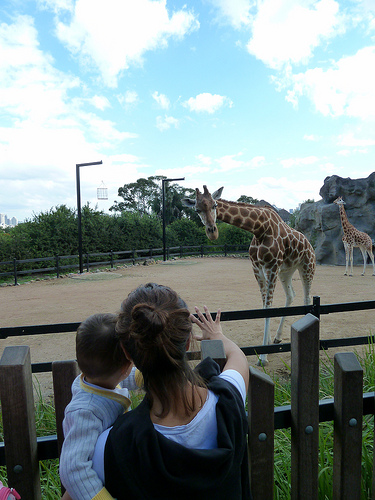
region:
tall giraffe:
[189, 191, 324, 291]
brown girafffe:
[321, 195, 367, 267]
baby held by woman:
[38, 310, 138, 476]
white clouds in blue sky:
[15, 13, 81, 86]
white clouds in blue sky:
[11, 70, 65, 134]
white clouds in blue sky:
[13, 132, 56, 185]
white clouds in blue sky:
[95, 32, 168, 139]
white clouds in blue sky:
[189, 105, 223, 141]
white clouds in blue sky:
[243, 42, 281, 91]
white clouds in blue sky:
[197, 95, 275, 152]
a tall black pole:
[73, 157, 112, 268]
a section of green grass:
[2, 355, 373, 498]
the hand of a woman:
[190, 306, 229, 341]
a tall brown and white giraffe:
[191, 181, 320, 369]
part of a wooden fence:
[0, 311, 373, 497]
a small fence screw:
[350, 418, 358, 426]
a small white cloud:
[182, 89, 229, 116]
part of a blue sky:
[168, 46, 219, 88]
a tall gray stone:
[289, 173, 372, 265]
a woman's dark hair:
[112, 280, 211, 422]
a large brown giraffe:
[181, 181, 321, 371]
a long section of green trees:
[0, 195, 257, 274]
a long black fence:
[0, 242, 230, 286]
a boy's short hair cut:
[74, 311, 126, 383]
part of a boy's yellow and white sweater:
[59, 368, 144, 499]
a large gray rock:
[294, 179, 373, 264]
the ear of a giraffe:
[181, 195, 194, 205]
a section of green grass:
[270, 350, 373, 499]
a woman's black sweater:
[101, 359, 258, 499]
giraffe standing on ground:
[182, 185, 314, 362]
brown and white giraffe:
[332, 197, 373, 275]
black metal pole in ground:
[75, 159, 103, 276]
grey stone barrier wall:
[298, 175, 374, 268]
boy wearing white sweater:
[58, 313, 144, 499]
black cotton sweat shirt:
[111, 363, 250, 498]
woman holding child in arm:
[62, 281, 257, 497]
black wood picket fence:
[2, 315, 372, 494]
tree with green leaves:
[115, 174, 177, 217]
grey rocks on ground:
[4, 271, 61, 287]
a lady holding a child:
[47, 281, 253, 497]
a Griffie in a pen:
[180, 181, 320, 359]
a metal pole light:
[74, 157, 109, 272]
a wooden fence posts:
[246, 313, 374, 493]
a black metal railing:
[237, 298, 373, 351]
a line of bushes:
[16, 222, 195, 272]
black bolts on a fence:
[254, 428, 270, 444]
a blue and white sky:
[15, 6, 372, 160]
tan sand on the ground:
[171, 260, 237, 291]